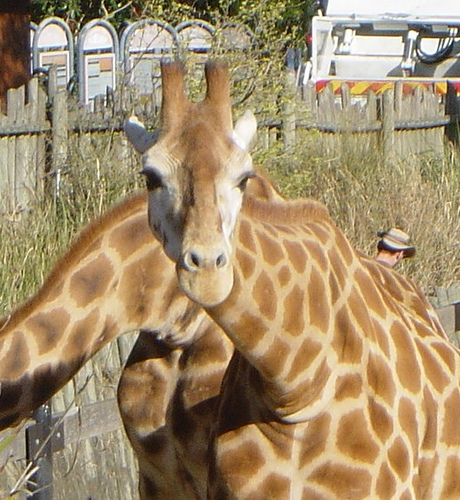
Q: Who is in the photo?
A: Two brown and tan giraffes.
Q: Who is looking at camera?
A: The giraffe.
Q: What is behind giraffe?
A: Fence.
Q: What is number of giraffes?
A: Two.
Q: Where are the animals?
A: In an enclosure.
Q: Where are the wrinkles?
A: On the neck.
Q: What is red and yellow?
A: Reflectors on truck.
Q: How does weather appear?
A: Sunny.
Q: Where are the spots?
A: On giraffe.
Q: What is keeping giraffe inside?
A: Wooden fence.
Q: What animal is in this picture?
A: Giraffe.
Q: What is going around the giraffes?
A: A fence.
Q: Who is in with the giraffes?
A: A man.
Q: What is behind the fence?
A: A truck.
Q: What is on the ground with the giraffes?
A: Long grass.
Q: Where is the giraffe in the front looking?
A: At the camera.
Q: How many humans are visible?
A: One.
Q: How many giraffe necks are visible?
A: Two.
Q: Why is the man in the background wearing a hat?
A: Protect from sun.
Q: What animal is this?
A: Giraffe.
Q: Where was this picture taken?
A: Zoo.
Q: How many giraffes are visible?
A: Two.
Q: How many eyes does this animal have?
A: Two.